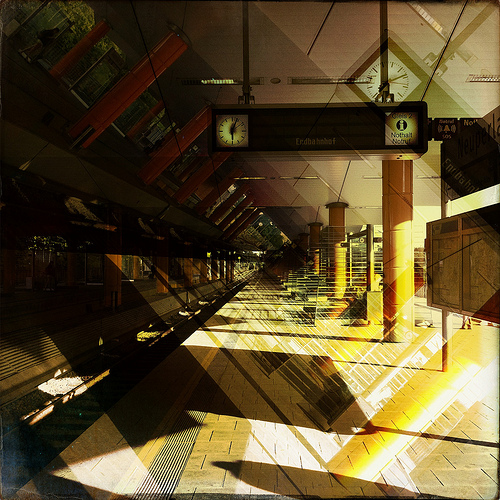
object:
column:
[378, 154, 416, 346]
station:
[1, 76, 500, 500]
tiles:
[407, 440, 462, 455]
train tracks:
[2, 319, 156, 433]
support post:
[364, 218, 376, 294]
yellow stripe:
[141, 362, 208, 471]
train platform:
[142, 270, 496, 484]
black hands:
[232, 117, 239, 131]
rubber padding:
[143, 328, 236, 494]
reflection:
[152, 346, 417, 436]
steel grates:
[138, 316, 243, 499]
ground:
[360, 294, 462, 484]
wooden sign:
[425, 207, 500, 320]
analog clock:
[215, 114, 249, 148]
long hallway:
[131, 250, 274, 384]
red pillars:
[63, 27, 194, 155]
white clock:
[349, 40, 428, 121]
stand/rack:
[307, 286, 384, 322]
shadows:
[123, 292, 366, 494]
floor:
[85, 275, 276, 484]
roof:
[15, 2, 236, 291]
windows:
[12, 0, 107, 72]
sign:
[209, 102, 427, 153]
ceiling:
[207, 3, 497, 212]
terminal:
[258, 220, 380, 319]